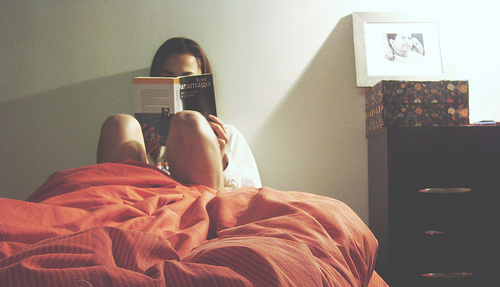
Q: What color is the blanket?
A: Red.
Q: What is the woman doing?
A: Reading a book.